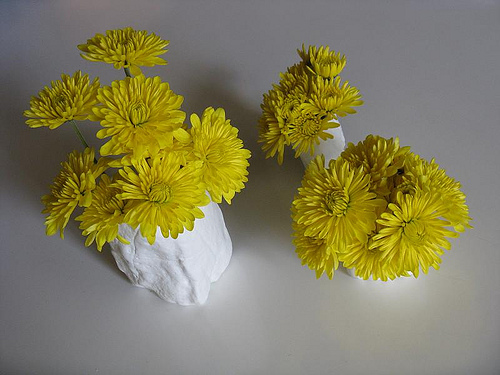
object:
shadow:
[5, 119, 43, 209]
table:
[4, 9, 85, 361]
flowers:
[285, 146, 457, 282]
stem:
[71, 123, 92, 151]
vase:
[103, 213, 258, 317]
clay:
[203, 227, 252, 275]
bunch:
[36, 17, 214, 288]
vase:
[286, 110, 353, 169]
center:
[148, 178, 176, 204]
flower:
[120, 154, 213, 243]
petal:
[118, 232, 132, 248]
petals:
[228, 151, 252, 187]